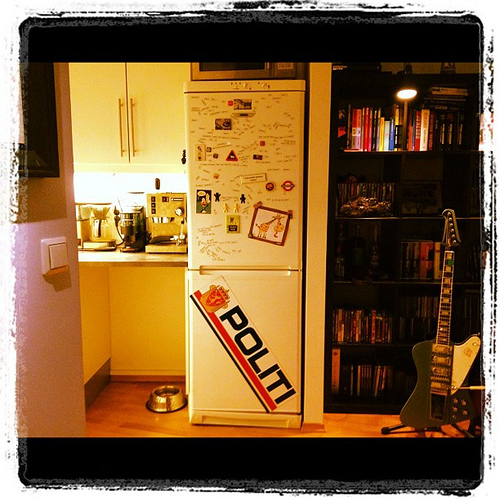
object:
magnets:
[195, 93, 303, 246]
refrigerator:
[182, 76, 303, 431]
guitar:
[393, 208, 483, 439]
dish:
[145, 384, 187, 413]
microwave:
[184, 60, 312, 82]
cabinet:
[67, 64, 194, 169]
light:
[394, 84, 420, 102]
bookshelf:
[328, 68, 487, 413]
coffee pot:
[119, 203, 148, 254]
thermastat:
[41, 236, 70, 276]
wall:
[24, 65, 89, 442]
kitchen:
[31, 28, 476, 473]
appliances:
[76, 201, 116, 249]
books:
[329, 308, 344, 343]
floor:
[96, 394, 139, 435]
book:
[350, 105, 361, 149]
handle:
[125, 93, 136, 162]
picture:
[21, 58, 67, 224]